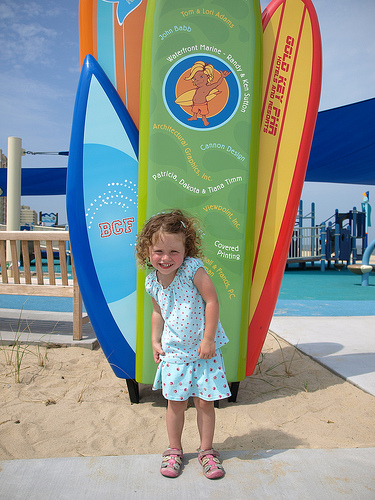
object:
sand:
[16, 356, 211, 486]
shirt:
[138, 257, 233, 362]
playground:
[302, 197, 373, 266]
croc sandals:
[198, 443, 226, 479]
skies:
[4, 30, 69, 134]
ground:
[272, 315, 375, 398]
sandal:
[145, 445, 267, 484]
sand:
[1, 323, 373, 451]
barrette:
[180, 219, 187, 228]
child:
[135, 207, 231, 478]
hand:
[198, 336, 216, 359]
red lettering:
[262, 34, 298, 139]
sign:
[249, 0, 322, 387]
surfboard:
[62, 53, 138, 375]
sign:
[135, 0, 263, 383]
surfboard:
[132, 1, 263, 385]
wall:
[40, 36, 91, 95]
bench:
[0, 230, 90, 341]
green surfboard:
[133, 0, 265, 387]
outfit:
[145, 255, 232, 402]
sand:
[0, 339, 373, 449]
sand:
[9, 359, 145, 456]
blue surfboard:
[64, 49, 139, 404]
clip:
[133, 209, 206, 270]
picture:
[161, 52, 242, 131]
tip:
[71, 49, 111, 85]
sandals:
[197, 447, 232, 474]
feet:
[159, 443, 183, 479]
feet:
[197, 445, 225, 480]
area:
[5, 312, 315, 456]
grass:
[2, 317, 54, 385]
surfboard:
[69, 52, 156, 354]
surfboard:
[135, 14, 265, 188]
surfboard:
[258, 5, 332, 376]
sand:
[280, 399, 349, 425]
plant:
[247, 319, 308, 378]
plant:
[11, 316, 65, 368]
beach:
[288, 249, 349, 271]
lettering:
[152, 170, 246, 196]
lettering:
[214, 240, 240, 261]